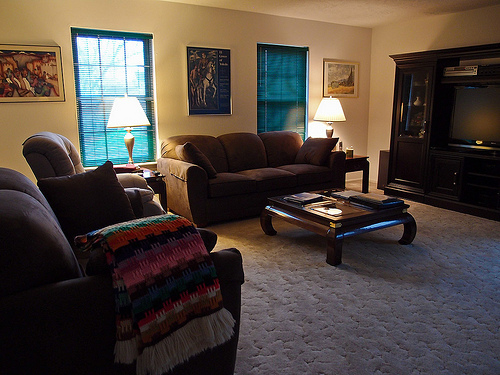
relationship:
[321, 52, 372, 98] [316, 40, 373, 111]
picture on wall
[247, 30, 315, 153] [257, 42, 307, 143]
window with blinds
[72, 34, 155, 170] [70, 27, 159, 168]
blinds on window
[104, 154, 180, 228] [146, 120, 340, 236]
end table on side of sofa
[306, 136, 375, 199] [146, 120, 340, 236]
end table on side of sofa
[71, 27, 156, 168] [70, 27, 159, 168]
blinds on window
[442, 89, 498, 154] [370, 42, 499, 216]
television built into cabinet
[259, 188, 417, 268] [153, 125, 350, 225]
coffe table next to couch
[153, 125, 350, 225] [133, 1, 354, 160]
couch against wall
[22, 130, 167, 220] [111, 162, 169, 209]
chair next to end table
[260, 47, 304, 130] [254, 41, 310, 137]
blinds hanging in window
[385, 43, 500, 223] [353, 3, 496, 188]
cabinet by wall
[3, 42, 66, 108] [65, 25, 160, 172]
painting next to window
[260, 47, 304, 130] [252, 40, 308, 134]
blinds are on window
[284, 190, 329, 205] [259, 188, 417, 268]
magazine on coffe table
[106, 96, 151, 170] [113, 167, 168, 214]
lamp on end table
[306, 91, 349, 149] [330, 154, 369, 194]
lamp on end table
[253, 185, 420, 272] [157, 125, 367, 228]
coffe table front sofa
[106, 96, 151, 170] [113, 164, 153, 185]
lamp on table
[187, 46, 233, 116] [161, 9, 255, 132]
artwork on wall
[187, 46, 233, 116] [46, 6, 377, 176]
artwork on wall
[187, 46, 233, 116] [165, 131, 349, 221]
artwork above couch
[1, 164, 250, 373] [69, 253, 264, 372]
chair has arm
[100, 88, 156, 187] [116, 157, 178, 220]
lamp on end table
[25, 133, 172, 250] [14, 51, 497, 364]
chair in living room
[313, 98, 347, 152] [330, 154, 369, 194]
lamp on end table